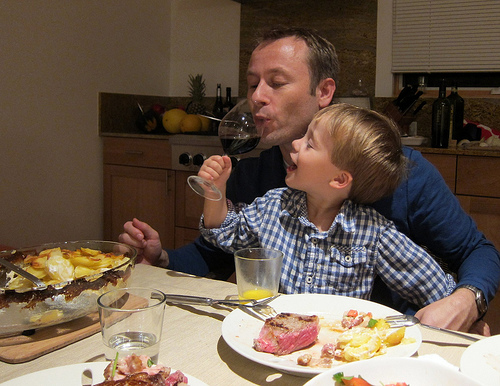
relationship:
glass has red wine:
[173, 92, 271, 203] [220, 134, 260, 153]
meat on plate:
[250, 309, 322, 354] [222, 286, 428, 371]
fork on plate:
[146, 283, 289, 316] [222, 286, 428, 371]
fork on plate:
[385, 313, 490, 344] [222, 286, 428, 371]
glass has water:
[92, 290, 165, 362] [102, 332, 165, 362]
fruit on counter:
[135, 75, 224, 136] [94, 89, 368, 141]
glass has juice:
[231, 246, 284, 304] [238, 289, 283, 300]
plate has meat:
[222, 286, 428, 371] [250, 310, 322, 356]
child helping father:
[215, 103, 464, 318] [115, 27, 498, 339]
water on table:
[102, 332, 165, 362] [5, 255, 499, 383]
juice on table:
[238, 289, 283, 300] [5, 255, 499, 383]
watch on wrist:
[451, 280, 491, 318] [456, 280, 496, 323]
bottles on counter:
[214, 84, 235, 131] [94, 89, 368, 141]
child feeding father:
[215, 103, 464, 318] [115, 27, 498, 339]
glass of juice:
[231, 246, 284, 304] [238, 289, 283, 300]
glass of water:
[92, 290, 165, 362] [102, 332, 165, 362]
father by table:
[115, 27, 498, 339] [5, 255, 499, 383]